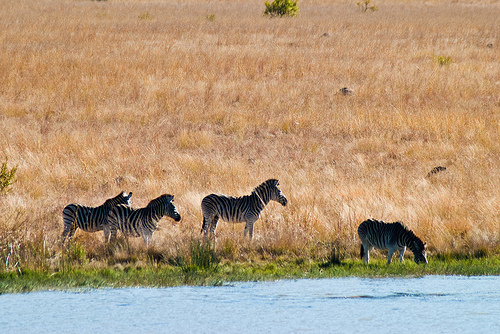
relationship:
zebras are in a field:
[48, 175, 468, 267] [1, 1, 499, 265]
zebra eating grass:
[348, 212, 439, 269] [398, 260, 497, 278]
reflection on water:
[398, 264, 442, 290] [1, 272, 499, 333]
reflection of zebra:
[398, 264, 442, 290] [348, 212, 439, 269]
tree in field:
[259, 2, 309, 21] [1, 1, 499, 265]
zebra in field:
[189, 181, 295, 245] [1, 1, 499, 265]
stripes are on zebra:
[205, 195, 258, 225] [189, 181, 295, 245]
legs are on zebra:
[353, 242, 407, 266] [348, 212, 439, 269]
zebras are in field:
[48, 175, 468, 267] [1, 1, 499, 265]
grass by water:
[398, 260, 497, 278] [1, 272, 499, 333]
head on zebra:
[257, 174, 291, 209] [189, 181, 295, 245]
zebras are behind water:
[48, 175, 468, 267] [1, 272, 499, 333]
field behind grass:
[1, 1, 499, 265] [398, 260, 497, 278]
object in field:
[413, 160, 458, 189] [1, 1, 499, 265]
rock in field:
[326, 80, 362, 107] [1, 1, 499, 265]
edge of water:
[50, 260, 481, 293] [1, 272, 499, 333]